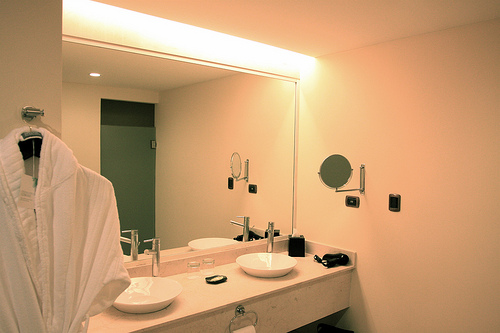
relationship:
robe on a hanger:
[1, 127, 130, 332] [21, 130, 43, 167]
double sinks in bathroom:
[237, 250, 297, 277] [1, 1, 498, 332]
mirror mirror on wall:
[61, 37, 297, 260] [1, 1, 498, 332]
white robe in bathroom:
[1, 127, 130, 332] [1, 1, 498, 332]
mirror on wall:
[61, 37, 297, 260] [1, 1, 498, 332]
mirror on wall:
[61, 37, 297, 260] [64, 1, 499, 332]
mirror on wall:
[319, 153, 366, 194] [64, 1, 499, 332]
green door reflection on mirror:
[99, 97, 158, 250] [61, 37, 297, 260]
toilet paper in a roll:
[232, 326, 258, 333] [232, 321, 260, 331]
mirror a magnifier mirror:
[61, 37, 297, 260] [227, 150, 251, 185]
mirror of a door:
[61, 37, 297, 260] [99, 97, 158, 250]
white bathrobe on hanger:
[1, 127, 130, 332] [21, 130, 43, 167]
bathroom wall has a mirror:
[64, 1, 499, 332] [61, 37, 297, 260]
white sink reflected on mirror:
[186, 235, 235, 250] [61, 37, 297, 260]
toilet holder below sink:
[227, 305, 255, 333] [237, 250, 297, 277]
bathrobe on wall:
[1, 127, 130, 332] [1, 1, 64, 129]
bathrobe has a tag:
[1, 127, 130, 332] [18, 175, 35, 210]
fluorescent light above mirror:
[64, 0, 320, 79] [61, 37, 297, 260]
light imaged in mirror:
[88, 71, 101, 81] [62, 34, 295, 270]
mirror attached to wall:
[319, 153, 366, 194] [299, 3, 497, 331]